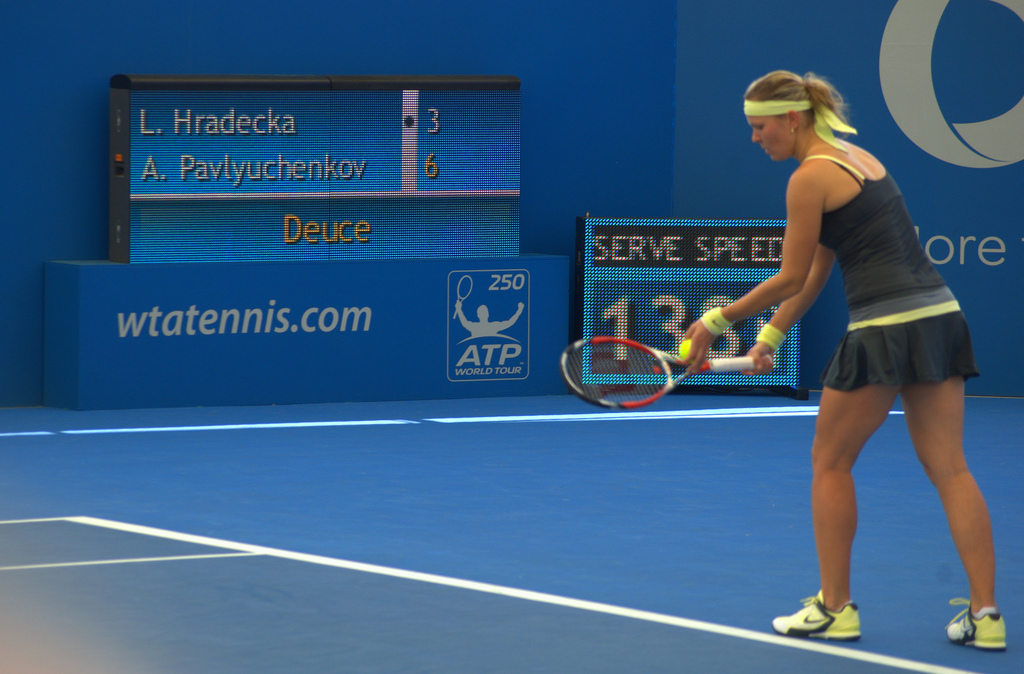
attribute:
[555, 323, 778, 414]
racket — red, white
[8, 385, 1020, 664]
floor — blue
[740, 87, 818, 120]
headband — yellow, tied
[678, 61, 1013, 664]
woman — smoking hot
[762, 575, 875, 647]
sneaker — nike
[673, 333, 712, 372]
ball — yellow, tennis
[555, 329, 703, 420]
racket — red, gray, and black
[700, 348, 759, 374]
handle — white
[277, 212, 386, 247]
word — orange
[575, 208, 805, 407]
sign — blue and black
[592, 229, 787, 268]
word — white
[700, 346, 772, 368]
racket handle — white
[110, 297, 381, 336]
lettering — gray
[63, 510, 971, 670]
line — white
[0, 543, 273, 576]
line — white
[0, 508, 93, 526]
line — white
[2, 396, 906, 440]
line — white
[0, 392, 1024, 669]
court — blue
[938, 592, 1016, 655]
shoe — yellow and white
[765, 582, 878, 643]
shoe — yellow and white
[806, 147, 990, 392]
tennis outfit — black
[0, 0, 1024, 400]
wall — blue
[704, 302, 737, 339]
wrist band — yellow 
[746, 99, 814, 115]
head band — yellow 